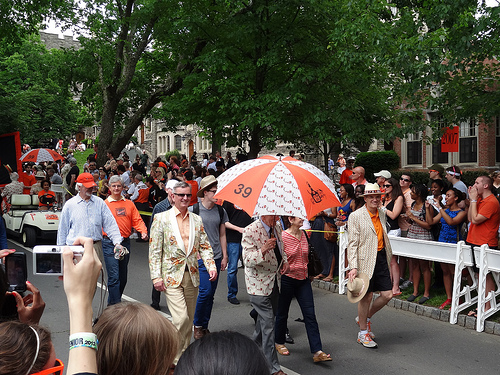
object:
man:
[241, 215, 290, 373]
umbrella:
[212, 155, 344, 239]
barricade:
[339, 225, 499, 333]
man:
[56, 171, 130, 264]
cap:
[75, 171, 98, 188]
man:
[348, 182, 395, 349]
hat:
[359, 181, 386, 197]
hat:
[346, 273, 371, 304]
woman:
[276, 216, 334, 364]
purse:
[302, 228, 324, 277]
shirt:
[280, 228, 313, 281]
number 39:
[234, 183, 253, 199]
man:
[149, 181, 221, 366]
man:
[103, 174, 149, 306]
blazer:
[241, 218, 289, 297]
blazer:
[346, 204, 394, 282]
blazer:
[149, 206, 218, 289]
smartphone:
[5, 250, 28, 294]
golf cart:
[2, 193, 63, 247]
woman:
[37, 179, 57, 212]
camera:
[33, 245, 88, 278]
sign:
[441, 125, 461, 165]